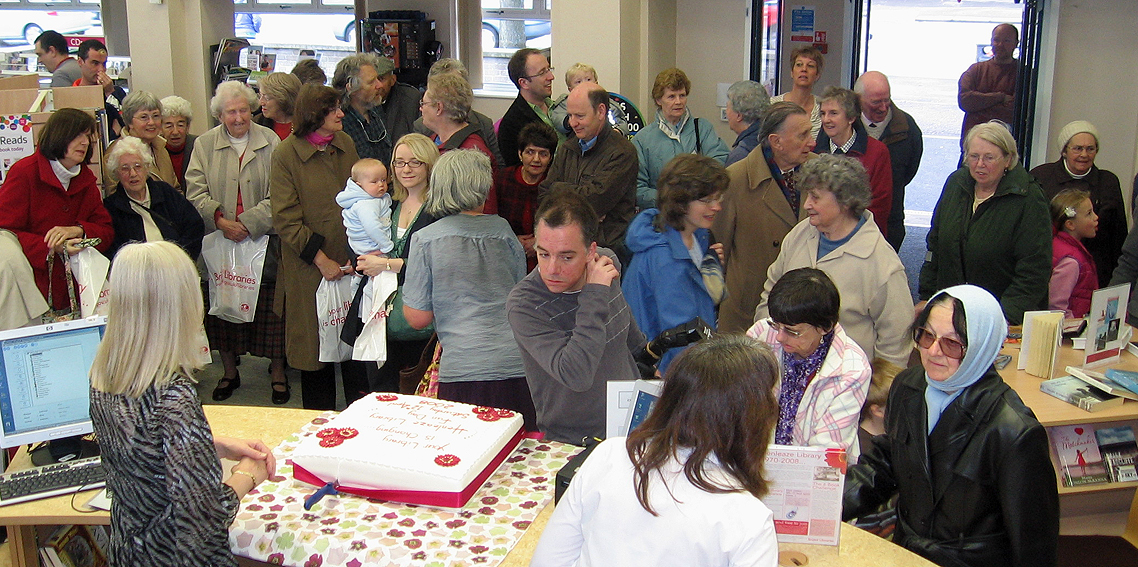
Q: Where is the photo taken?
A: A house.